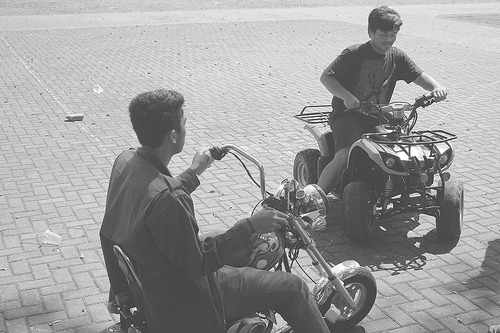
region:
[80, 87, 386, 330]
a boy on a bicycle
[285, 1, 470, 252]
a boy on a cart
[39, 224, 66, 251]
a cup on the ground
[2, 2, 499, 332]
bricks on the ground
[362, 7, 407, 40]
his hair is bushy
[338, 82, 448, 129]
his hands are gripping the handles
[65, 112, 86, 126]
rocks on the ground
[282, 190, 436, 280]
the cart shadow on the ground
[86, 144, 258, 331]
he is wearing a collar shirt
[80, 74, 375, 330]
the boy is looking at the other boy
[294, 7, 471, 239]
The person riding a quad bike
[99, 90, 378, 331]
The person riding a motorbike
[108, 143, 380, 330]
The low riding motor bike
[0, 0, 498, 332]
The open gray space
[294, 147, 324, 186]
The quad bike rear wheel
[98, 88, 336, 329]
The rider in the left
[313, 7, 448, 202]
The rider in the right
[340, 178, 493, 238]
The two tyres on the right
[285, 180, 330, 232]
The bike head lamp on the right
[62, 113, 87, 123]
A piece of stone laying on the ground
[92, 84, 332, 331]
Young man riding on motorbike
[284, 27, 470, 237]
Young man riding on ATV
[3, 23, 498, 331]
Brick surface under vehicles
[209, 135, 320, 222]
Handlebars of motorbike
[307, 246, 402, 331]
Small rubber tire of vehicle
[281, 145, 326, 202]
Small rubber tire of vehicle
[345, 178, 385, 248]
Small rubber tire of vehicle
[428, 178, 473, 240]
Small rubber tire of vehicle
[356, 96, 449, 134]
Handlebars of ATV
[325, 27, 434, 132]
Tshirt on boy driving atv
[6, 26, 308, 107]
brick covering the ground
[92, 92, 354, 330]
man sitting on a motorcycle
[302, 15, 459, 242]
man sitting on ATV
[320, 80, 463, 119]
two hand gripping handlebars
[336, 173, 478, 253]
tires turned to the side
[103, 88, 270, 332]
man wearing a jacket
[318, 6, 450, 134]
man smiling on ATV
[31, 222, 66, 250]
trash scattered on ground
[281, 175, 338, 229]
shiny metal headlight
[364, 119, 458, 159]
storage rack on ATV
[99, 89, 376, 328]
person on a low rider bike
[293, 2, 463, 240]
person on a four wheeler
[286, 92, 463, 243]
four wheeler vehicle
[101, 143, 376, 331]
low rider vehicle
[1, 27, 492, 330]
brick pavers on the ground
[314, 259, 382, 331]
front wheel of the bike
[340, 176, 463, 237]
front wheels of the four wheeler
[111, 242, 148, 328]
seat back of the low rider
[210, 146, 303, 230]
front handles of the low rider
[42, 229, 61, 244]
plastic cup laying on the ground